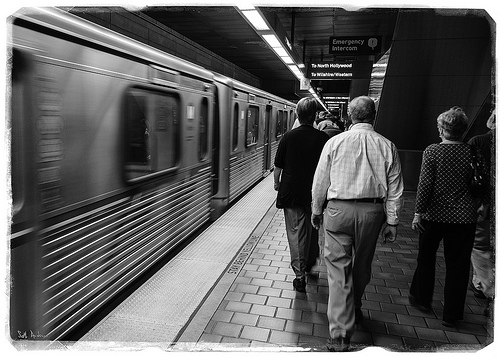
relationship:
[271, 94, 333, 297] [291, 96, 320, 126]
person has head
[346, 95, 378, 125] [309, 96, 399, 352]
head of man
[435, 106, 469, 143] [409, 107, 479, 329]
head of woman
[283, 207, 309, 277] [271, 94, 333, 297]
leg of person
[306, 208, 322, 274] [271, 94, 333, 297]
leg of person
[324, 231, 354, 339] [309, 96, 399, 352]
leg of man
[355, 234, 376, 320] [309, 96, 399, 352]
leg of man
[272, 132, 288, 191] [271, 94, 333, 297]
arm of person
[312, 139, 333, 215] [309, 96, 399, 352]
arm of man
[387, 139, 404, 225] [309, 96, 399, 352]
arm of man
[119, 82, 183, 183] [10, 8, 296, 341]
window on train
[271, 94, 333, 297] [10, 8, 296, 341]
person alongside train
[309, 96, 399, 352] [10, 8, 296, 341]
man alongside train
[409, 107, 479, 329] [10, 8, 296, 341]
woman alongside train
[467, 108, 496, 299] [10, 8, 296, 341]
woman alongside train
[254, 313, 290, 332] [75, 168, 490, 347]
tile on floor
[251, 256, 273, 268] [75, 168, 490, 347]
tile on floor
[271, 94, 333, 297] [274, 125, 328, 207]
person wearing shirt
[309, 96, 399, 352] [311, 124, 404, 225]
man wearing shirt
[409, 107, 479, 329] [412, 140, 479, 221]
woman wearing shirt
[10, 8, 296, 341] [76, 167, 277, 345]
train alongside zone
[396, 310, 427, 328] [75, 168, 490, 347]
brick on floor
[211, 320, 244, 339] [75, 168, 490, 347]
tile on floor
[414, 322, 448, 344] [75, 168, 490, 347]
tile in floor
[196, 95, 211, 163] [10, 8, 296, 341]
window on train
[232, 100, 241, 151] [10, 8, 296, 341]
window on train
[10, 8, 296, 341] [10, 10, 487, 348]
train in station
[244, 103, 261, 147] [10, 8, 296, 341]
window on train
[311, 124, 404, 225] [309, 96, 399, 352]
shirt on man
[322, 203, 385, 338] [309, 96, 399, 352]
pants on man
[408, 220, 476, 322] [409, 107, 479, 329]
pants on woman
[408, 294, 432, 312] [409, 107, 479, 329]
shoe on woman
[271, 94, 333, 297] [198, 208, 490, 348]
person on floor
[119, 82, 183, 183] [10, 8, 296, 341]
window of train